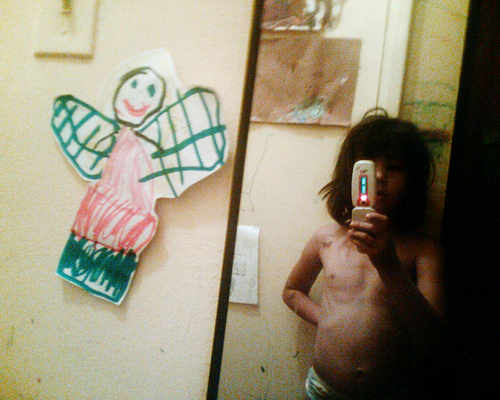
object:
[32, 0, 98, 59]
light switch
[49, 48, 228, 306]
paper drawing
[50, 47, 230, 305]
angel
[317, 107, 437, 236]
hair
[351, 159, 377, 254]
cellphone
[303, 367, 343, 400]
underware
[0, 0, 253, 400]
wall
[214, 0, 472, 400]
wall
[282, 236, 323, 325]
arm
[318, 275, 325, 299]
back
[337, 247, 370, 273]
chest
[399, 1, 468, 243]
curtain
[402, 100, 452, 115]
stripes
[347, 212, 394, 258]
hand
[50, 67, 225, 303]
drawing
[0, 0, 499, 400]
picture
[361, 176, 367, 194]
light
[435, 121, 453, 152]
marks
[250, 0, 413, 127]
paper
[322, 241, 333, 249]
tattoo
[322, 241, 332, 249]
butterfly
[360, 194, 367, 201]
lights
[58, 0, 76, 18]
partial light switch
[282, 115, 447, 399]
child